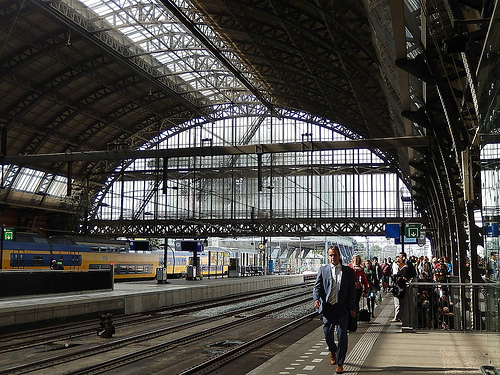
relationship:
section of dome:
[295, 48, 341, 91] [3, 0, 398, 126]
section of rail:
[16, 314, 115, 361] [0, 277, 351, 374]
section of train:
[195, 253, 241, 271] [10, 247, 278, 276]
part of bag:
[364, 316, 374, 319] [357, 306, 374, 326]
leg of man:
[321, 323, 335, 348] [312, 247, 361, 363]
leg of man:
[336, 325, 357, 360] [312, 247, 361, 363]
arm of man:
[310, 276, 322, 299] [312, 247, 361, 363]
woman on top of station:
[351, 248, 377, 295] [266, 213, 448, 370]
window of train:
[32, 255, 44, 265] [10, 247, 278, 276]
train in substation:
[10, 247, 278, 276] [3, 223, 293, 316]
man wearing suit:
[312, 247, 361, 363] [307, 264, 351, 323]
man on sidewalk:
[312, 247, 361, 363] [272, 341, 316, 371]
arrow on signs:
[409, 230, 420, 238] [399, 224, 428, 244]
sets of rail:
[182, 300, 288, 346] [0, 277, 351, 374]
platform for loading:
[244, 339, 318, 374] [341, 280, 468, 330]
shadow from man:
[345, 359, 474, 372] [312, 247, 361, 363]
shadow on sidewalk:
[345, 359, 474, 372] [272, 341, 316, 371]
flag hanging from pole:
[382, 222, 400, 243] [402, 219, 408, 254]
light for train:
[3, 233, 24, 242] [10, 247, 278, 276]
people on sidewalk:
[334, 244, 445, 308] [272, 341, 316, 371]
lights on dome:
[132, 22, 225, 68] [3, 0, 398, 126]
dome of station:
[3, 0, 398, 126] [266, 213, 448, 370]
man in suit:
[312, 247, 361, 363] [307, 264, 351, 323]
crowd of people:
[355, 253, 446, 299] [334, 244, 445, 308]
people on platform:
[334, 244, 445, 308] [244, 339, 318, 374]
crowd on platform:
[355, 253, 446, 299] [244, 339, 318, 374]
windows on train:
[6, 249, 145, 270] [10, 247, 278, 276]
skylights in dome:
[173, 42, 251, 101] [3, 0, 398, 126]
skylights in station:
[173, 42, 251, 101] [266, 213, 448, 370]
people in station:
[334, 244, 445, 308] [266, 213, 448, 370]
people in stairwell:
[334, 244, 445, 308] [408, 292, 472, 327]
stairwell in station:
[408, 292, 472, 327] [266, 213, 448, 370]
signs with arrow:
[399, 224, 428, 244] [409, 230, 420, 238]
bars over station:
[161, 117, 363, 152] [266, 213, 448, 370]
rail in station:
[0, 277, 351, 374] [266, 213, 448, 370]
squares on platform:
[301, 355, 322, 370] [244, 339, 318, 374]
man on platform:
[312, 247, 361, 363] [244, 339, 318, 374]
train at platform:
[10, 247, 278, 276] [244, 339, 318, 374]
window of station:
[32, 255, 44, 265] [266, 213, 448, 370]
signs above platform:
[378, 219, 428, 244] [244, 339, 318, 374]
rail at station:
[0, 277, 351, 374] [266, 213, 448, 370]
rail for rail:
[0, 277, 351, 374] [220, 309, 289, 340]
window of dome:
[32, 255, 44, 265] [165, 57, 302, 139]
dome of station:
[165, 57, 302, 139] [266, 213, 448, 370]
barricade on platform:
[397, 281, 490, 326] [244, 339, 318, 374]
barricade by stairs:
[397, 281, 490, 326] [428, 297, 481, 322]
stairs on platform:
[428, 297, 481, 322] [244, 339, 318, 374]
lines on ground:
[291, 355, 312, 361] [244, 339, 318, 374]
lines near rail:
[291, 355, 312, 361] [0, 277, 351, 374]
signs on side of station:
[399, 224, 428, 244] [266, 213, 448, 370]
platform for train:
[244, 339, 318, 374] [10, 247, 278, 276]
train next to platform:
[10, 247, 278, 276] [244, 339, 318, 374]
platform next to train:
[244, 339, 318, 374] [10, 247, 278, 276]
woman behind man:
[351, 248, 377, 295] [312, 247, 361, 363]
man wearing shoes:
[312, 247, 361, 363] [325, 352, 348, 373]